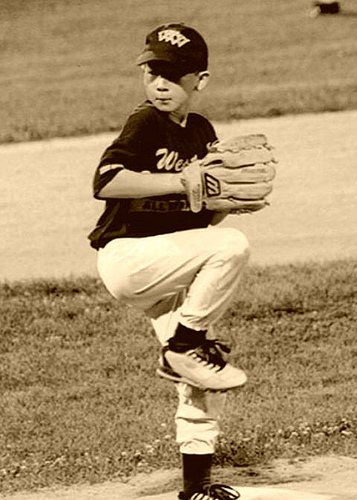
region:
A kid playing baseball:
[94, 57, 273, 346]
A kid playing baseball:
[129, 213, 221, 439]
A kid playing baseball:
[168, 298, 245, 470]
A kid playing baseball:
[165, 219, 210, 390]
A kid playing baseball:
[75, 163, 301, 460]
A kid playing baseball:
[122, 179, 175, 358]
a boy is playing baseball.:
[84, 18, 250, 498]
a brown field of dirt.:
[274, 413, 345, 476]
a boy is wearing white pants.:
[72, 233, 273, 311]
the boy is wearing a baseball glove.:
[176, 125, 291, 235]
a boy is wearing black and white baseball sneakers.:
[153, 346, 246, 400]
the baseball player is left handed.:
[89, 125, 198, 232]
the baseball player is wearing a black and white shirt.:
[88, 105, 233, 174]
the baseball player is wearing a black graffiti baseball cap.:
[129, 18, 221, 70]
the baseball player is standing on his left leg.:
[158, 394, 238, 497]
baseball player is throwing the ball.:
[86, 26, 260, 498]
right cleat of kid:
[150, 314, 283, 423]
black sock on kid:
[150, 431, 225, 486]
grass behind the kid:
[39, 352, 152, 445]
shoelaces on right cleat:
[191, 339, 238, 377]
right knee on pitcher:
[205, 239, 268, 282]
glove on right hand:
[189, 191, 307, 236]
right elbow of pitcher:
[88, 153, 170, 209]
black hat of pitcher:
[104, 9, 265, 90]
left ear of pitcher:
[185, 61, 217, 94]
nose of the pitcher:
[149, 75, 176, 93]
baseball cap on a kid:
[130, 13, 215, 117]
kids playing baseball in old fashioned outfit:
[68, 19, 294, 427]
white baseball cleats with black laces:
[152, 339, 262, 398]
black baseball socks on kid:
[168, 444, 221, 491]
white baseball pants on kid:
[97, 231, 276, 462]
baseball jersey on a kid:
[85, 101, 239, 227]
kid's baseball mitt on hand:
[178, 120, 288, 211]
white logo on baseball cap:
[158, 24, 195, 51]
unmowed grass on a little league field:
[40, 381, 113, 454]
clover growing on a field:
[271, 418, 352, 450]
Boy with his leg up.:
[94, 228, 254, 399]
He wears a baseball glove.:
[176, 121, 276, 212]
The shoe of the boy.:
[148, 340, 257, 396]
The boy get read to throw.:
[83, 1, 285, 498]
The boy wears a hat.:
[133, 16, 207, 71]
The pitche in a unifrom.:
[100, 2, 270, 498]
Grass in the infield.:
[25, 287, 90, 473]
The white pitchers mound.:
[222, 481, 330, 498]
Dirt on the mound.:
[47, 478, 176, 497]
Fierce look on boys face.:
[134, 19, 215, 117]